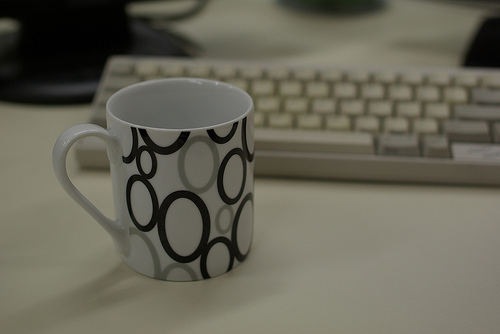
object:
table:
[0, 0, 496, 332]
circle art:
[217, 144, 247, 209]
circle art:
[213, 202, 235, 234]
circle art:
[125, 171, 160, 232]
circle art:
[135, 128, 190, 156]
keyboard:
[99, 42, 499, 222]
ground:
[392, 197, 419, 244]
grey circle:
[175, 134, 221, 190]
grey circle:
[159, 262, 197, 282]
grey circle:
[126, 228, 161, 279]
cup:
[99, 86, 259, 281]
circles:
[132, 139, 251, 265]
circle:
[178, 135, 218, 192]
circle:
[157, 192, 209, 258]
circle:
[198, 237, 233, 275]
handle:
[52, 122, 129, 242]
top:
[107, 77, 253, 130]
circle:
[135, 145, 157, 178]